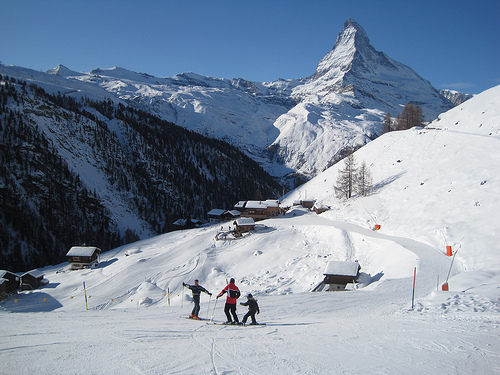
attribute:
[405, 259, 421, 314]
pole — multi colored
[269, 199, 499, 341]
snow — white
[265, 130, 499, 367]
slope — snow covered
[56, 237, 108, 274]
building — small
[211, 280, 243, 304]
coat — red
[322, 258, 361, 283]
cabin — small, ski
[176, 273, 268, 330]
slope — snow covered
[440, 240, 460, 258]
flag — orange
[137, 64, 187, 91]
mountain ridge — snow covered, large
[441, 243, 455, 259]
marker — orange, road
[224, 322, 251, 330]
skis — alpine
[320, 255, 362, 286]
house — small, snow covered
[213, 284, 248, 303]
jacket — orange